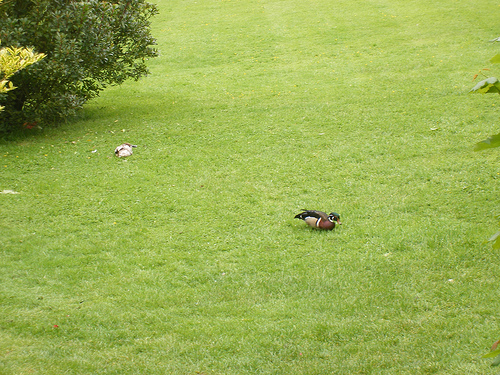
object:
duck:
[293, 208, 341, 234]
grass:
[0, 0, 500, 375]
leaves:
[110, 130, 115, 134]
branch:
[80, 13, 121, 52]